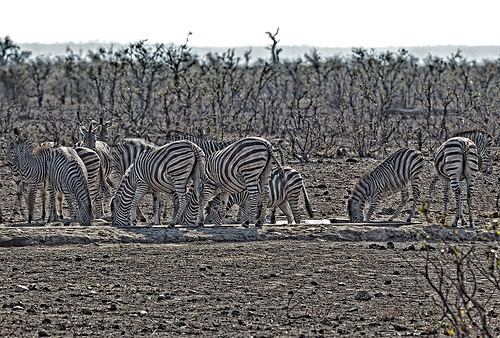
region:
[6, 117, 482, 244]
A large group of zebras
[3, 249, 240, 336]
barren soil with little moisture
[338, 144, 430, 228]
a zebra takes a drink of water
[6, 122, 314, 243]
zebras congregate in a herd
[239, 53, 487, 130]
a section of shrubbery with little life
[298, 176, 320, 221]
the tail of a zebra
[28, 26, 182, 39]
foggy skyline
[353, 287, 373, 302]
a rock on the ground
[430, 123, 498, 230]
zebra looking to it's right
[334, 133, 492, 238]
two zebras relaxing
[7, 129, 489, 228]
The zebras drinking water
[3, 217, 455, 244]
The small pool of water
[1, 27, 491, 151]
Small scrubby trees behind the animals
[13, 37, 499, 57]
Hills in the background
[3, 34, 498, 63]
The horizon line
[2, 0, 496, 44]
Open sky above the horizon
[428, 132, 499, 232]
Zebra by itself on the right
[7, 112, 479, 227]
Group of animals at a watering hole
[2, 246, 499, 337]
Open dirt between photographer and animals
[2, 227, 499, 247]
Rock formation around water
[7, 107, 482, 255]
zebras camouflaged by surroundings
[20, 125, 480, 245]
zebras feeding or drinking from enclosure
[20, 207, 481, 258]
stone rim around enclosure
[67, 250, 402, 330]
rocky and dry soil of environment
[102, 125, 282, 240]
zebras standing side to side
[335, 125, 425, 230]
zebra bending deeply while supported by hind legs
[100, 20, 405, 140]
stems and branches with little vegetation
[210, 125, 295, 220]
tail swinging to side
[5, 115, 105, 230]
two zebras with their heads up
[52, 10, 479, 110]
line of mountains at the horizon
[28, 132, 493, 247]
Zebras bending over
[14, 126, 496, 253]
Herd of zebras by each other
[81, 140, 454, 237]
Black and white stripes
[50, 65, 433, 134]
Trees in background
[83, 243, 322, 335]
Small rocks on the ground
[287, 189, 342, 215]
Black hair on the tip of tail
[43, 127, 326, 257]
Zebras eating off the ground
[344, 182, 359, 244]
Black fur on zebra's head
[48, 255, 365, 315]
Ground is gray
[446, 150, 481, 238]
Stripes on back legs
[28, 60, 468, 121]
a group of small trees without leaves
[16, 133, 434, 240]
a herd of zebra appearing to be at a watering hole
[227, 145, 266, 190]
zebra stripes on the hind quarter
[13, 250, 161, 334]
stoney soil void of vegetation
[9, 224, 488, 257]
raised edge of a watering area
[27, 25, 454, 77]
distant row of hills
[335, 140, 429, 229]
A young zebra drinking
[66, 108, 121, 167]
a zebra watching the photographer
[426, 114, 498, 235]
The end zebra watches to the right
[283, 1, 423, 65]
The sky appears to be hazy